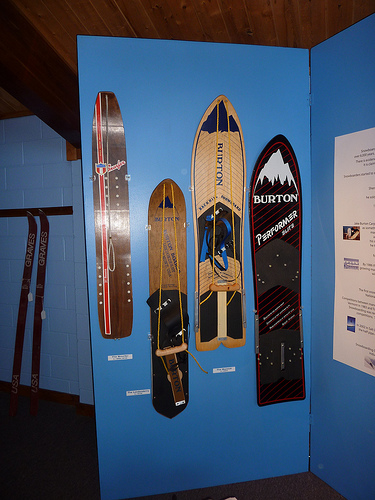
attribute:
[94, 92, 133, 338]
skateboard — red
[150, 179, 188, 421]
skateboard — brown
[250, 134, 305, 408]
skateboard — black, white, red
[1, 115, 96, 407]
wall — blue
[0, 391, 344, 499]
ground — black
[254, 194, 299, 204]
burton — white